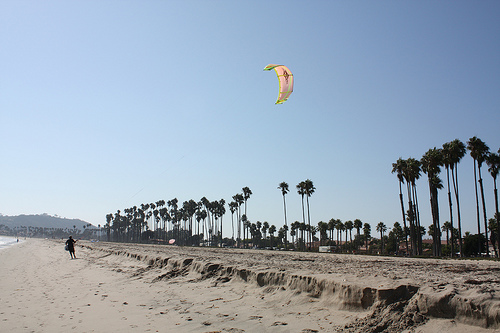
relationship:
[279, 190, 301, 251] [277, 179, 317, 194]
skinny trunk of a palm tree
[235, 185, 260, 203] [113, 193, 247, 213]
leaves of some palm trees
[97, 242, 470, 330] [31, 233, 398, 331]
ledge made by sand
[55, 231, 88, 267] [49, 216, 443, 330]
guy standing standing on beach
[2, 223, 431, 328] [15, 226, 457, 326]
shore of the beach of beach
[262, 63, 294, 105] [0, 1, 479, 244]
fabric in the air in sky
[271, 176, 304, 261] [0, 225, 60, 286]
"a palm tree on edge of beach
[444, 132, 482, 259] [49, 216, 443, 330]
palm tree on the on edge of beach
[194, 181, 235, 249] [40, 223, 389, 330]
palm trees on beach on edge of beach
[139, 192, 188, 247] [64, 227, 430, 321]
palm trees on beach on edge of beach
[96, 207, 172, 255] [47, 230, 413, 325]
trees on the edge on edge of beach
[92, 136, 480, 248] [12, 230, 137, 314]
trees on edge a beach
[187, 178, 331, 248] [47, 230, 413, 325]
trees on the edge on edge of beach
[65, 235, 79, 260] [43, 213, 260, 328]
guy standing on beach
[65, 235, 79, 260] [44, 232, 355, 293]
guy standing on beach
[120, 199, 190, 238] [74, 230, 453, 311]
trees on the beach along beach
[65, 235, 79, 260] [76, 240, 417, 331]
guy standing on beach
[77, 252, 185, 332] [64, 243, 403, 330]
area of the beach of beach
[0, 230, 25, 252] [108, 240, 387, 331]
water area of beach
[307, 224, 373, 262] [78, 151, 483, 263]
buildings behind behind trees